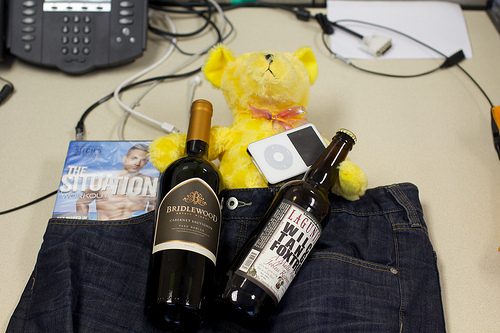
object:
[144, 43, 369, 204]
teddy bear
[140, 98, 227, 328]
bottles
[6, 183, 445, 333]
jeans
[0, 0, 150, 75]
telephone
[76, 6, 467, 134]
cables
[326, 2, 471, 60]
paper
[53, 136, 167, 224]
dvd case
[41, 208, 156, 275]
jeans pocket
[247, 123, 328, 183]
ipod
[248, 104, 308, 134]
bow tie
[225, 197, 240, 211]
button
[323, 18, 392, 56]
cable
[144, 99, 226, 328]
wine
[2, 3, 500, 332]
table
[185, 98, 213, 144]
wrapping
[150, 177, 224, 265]
label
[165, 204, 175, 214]
writing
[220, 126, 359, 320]
bottle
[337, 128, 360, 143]
cap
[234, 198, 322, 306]
label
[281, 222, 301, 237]
writing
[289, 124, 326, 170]
dark screen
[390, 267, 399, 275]
rivet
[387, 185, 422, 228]
belt loop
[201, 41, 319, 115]
head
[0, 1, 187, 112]
upper left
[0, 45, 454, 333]
items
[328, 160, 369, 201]
paw